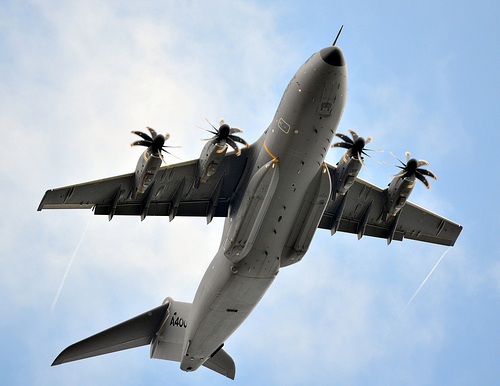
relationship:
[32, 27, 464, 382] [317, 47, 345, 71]
airplane has nose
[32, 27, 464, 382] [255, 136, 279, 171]
airplane has strip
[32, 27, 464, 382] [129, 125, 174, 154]
airplane has blades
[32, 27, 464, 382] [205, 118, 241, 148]
airplane has blades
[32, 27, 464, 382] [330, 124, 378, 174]
airplane has propeller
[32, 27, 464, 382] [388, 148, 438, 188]
airplane has propeller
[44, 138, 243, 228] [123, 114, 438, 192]
wing has propellers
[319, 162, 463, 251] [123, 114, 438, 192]
wing has propellers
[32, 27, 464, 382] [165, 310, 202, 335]
airplane has letters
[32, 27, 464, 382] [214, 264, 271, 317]
airplane has landing wheel cover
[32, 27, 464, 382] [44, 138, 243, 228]
airplane has wing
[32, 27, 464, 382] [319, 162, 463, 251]
airplane has wing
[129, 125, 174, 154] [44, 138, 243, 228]
blades on wing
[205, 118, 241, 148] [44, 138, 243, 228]
blades on wing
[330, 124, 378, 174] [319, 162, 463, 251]
propeller on wing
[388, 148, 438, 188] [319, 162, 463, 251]
propeller on wing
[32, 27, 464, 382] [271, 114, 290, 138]
airplane has door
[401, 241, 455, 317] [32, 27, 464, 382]
jetstream coming from airplane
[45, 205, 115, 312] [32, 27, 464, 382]
jetstream coming from airplane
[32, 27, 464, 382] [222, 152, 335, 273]
airplane has stabilizers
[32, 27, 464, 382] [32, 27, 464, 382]
airplane called airplane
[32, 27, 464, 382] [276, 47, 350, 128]
airplane has cockpit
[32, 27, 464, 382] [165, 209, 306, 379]
airplane has fuselage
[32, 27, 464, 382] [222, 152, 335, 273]
airplane has landing gear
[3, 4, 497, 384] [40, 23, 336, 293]
sky has clouds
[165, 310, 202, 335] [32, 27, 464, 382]
letters on airplane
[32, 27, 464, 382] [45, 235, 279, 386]
airplane has tail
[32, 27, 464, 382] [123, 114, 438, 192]
airplane has propellers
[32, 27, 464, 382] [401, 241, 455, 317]
airplane has jetstream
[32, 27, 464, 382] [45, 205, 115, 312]
airplane has jetstream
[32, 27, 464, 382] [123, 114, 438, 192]
airplane has motors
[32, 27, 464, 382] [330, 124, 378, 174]
airplane has engine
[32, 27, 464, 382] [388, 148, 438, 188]
airplane has engine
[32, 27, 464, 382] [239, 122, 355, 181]
airplane has highlights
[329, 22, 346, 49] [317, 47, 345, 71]
antenna on nose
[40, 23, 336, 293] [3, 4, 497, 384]
clouds in sky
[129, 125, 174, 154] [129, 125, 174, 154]
blades on blades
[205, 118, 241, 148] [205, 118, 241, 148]
blades on blades